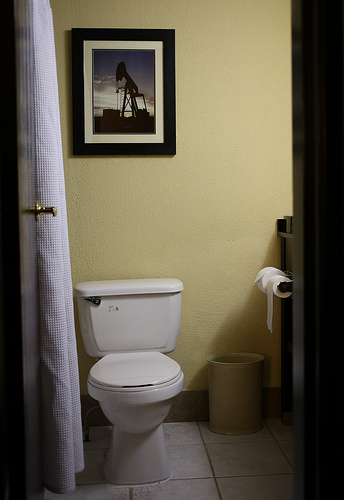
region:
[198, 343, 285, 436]
trash can under toilet paper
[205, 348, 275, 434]
trash can is round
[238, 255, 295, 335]
two rolls of toilet paper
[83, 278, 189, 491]
toilet is white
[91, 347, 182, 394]
toilet seat is down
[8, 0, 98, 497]
shower curtain is blue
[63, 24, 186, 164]
picture behind the toilet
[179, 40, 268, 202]
wall is yellow and textured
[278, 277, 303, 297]
toilet paper holder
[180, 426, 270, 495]
tiles on the floor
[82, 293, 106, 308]
A small metal handle on the toilet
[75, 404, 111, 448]
A thin metal wire behind the toilet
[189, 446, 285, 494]
Dirty white tiling on the bathroom floor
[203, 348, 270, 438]
A small white waste basket in the bathroom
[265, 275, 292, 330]
An unwraveled roll of toilet paper next to the larger roll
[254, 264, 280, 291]
A large roll of toilet paper near the wall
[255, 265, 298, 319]
Two rolls of toilet paper above the trash can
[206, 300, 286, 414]
A shadow on the bathroom wall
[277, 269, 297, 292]
The metal toilet paper holders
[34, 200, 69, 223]
A brass doorknob on the white door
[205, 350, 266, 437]
tan colored trash can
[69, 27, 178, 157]
picture of oil rig hanging on the wall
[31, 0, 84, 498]
shower curtain hanging next to the curtain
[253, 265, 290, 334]
toilet paper hanging beside the trash can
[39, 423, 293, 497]
tile flooring with brown grout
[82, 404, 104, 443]
water pipe leading into the toilet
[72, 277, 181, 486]
white porcelain toilet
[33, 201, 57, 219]
gold colored door knob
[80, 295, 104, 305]
black colored toilet handle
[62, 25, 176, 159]
shadow of the frame on the left side and bottom of the picture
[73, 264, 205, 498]
white toilet in bathroom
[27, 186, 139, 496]
shower curtain next to toilet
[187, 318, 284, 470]
brown wastebasket on floor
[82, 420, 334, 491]
white tiles on bathroom floor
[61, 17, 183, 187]
black framed picture on wall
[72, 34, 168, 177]
white border around picture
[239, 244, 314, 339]
two rolls of toilet paper on holders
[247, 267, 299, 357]
toilet paper hanging down from roll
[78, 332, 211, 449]
lid closed on toilet seat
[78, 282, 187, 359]
dark handle on white toilet tank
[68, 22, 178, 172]
black picture frame on wall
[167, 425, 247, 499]
tiles are light grey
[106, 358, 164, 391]
toilet seat cover is down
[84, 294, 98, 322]
metal toilet flush handle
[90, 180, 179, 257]
yellow wall behind toilet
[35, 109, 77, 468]
white cloth shower curtain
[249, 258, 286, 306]
two white toilet rolls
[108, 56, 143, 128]
oil rig in framed picture